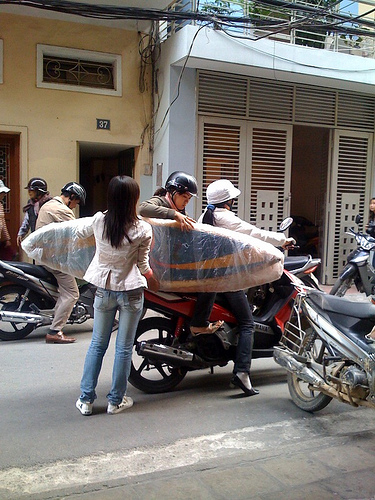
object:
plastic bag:
[21, 215, 96, 280]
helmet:
[60, 181, 86, 206]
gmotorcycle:
[125, 216, 306, 393]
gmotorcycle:
[0, 259, 96, 341]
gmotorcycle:
[273, 282, 374, 412]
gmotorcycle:
[329, 213, 374, 303]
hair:
[101, 176, 140, 250]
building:
[0, 0, 373, 286]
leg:
[111, 302, 142, 396]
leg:
[219, 290, 254, 376]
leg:
[190, 280, 218, 325]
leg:
[80, 288, 116, 399]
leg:
[50, 269, 81, 329]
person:
[16, 177, 51, 249]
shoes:
[75, 397, 134, 416]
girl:
[75, 176, 161, 416]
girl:
[138, 170, 224, 338]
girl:
[197, 179, 296, 395]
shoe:
[231, 373, 261, 396]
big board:
[21, 213, 283, 293]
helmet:
[164, 171, 199, 200]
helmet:
[24, 177, 48, 193]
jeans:
[80, 288, 145, 406]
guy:
[35, 181, 86, 344]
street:
[1, 307, 373, 499]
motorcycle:
[282, 254, 322, 290]